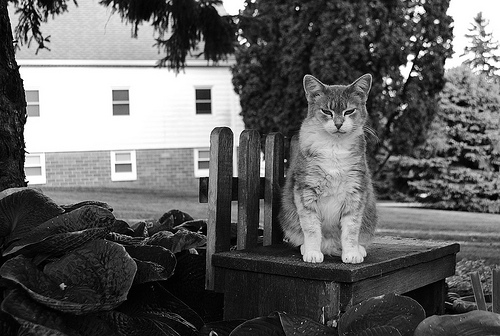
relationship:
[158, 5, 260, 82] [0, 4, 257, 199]
limbs hanging from tree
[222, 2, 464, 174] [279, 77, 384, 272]
tree behind cat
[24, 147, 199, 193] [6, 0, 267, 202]
wall on building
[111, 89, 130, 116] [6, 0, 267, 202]
window on building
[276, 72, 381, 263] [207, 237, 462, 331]
car sitting on table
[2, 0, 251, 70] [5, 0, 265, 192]
roof on building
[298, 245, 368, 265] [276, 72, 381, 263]
paws on car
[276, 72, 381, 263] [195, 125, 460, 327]
car on chair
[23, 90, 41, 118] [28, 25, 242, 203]
window on building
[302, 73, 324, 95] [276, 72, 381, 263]
ear on car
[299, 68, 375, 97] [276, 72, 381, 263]
ears on car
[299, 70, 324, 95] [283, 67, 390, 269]
ear on car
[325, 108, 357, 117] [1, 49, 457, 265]
eyes looking at camera